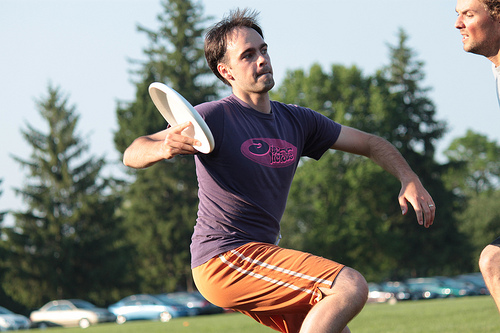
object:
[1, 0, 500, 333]
scene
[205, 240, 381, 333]
leg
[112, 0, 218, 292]
pine tree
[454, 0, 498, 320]
someone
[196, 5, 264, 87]
hair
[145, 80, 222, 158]
frisbee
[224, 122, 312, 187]
logo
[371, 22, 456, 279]
trees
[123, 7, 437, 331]
white male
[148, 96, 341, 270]
purple shirt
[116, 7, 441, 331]
man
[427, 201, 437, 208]
ring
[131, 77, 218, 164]
frisbee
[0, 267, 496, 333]
car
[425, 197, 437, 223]
finger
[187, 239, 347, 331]
short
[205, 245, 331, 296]
stripe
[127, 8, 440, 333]
male